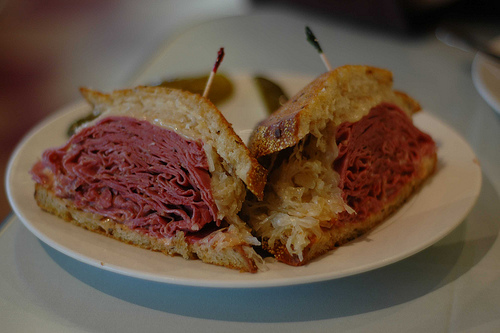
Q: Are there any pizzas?
A: No, there are no pizzas.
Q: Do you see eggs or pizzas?
A: No, there are no pizzas or eggs.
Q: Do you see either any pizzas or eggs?
A: No, there are no pizzas or eggs.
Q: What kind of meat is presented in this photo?
A: The meat is ham.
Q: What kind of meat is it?
A: The meat is ham.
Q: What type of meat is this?
A: This is ham.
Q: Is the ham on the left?
A: Yes, the ham is on the left of the image.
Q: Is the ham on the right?
A: No, the ham is on the left of the image.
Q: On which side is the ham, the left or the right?
A: The ham is on the left of the image.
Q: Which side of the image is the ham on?
A: The ham is on the left of the image.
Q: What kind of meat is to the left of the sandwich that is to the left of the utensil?
A: The meat is ham.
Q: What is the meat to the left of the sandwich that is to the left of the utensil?
A: The meat is ham.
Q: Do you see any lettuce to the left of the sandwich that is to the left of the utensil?
A: No, there is ham to the left of the sandwich.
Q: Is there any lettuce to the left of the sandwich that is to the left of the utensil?
A: No, there is ham to the left of the sandwich.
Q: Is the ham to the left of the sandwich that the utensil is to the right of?
A: Yes, the ham is to the left of the sandwich.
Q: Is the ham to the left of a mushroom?
A: No, the ham is to the left of the sandwich.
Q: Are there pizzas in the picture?
A: No, there are no pizzas.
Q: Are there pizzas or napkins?
A: No, there are no pizzas or napkins.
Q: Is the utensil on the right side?
A: Yes, the utensil is on the right of the image.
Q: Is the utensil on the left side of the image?
A: No, the utensil is on the right of the image.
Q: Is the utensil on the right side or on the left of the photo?
A: The utensil is on the right of the image.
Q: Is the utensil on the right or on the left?
A: The utensil is on the right of the image.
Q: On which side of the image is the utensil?
A: The utensil is on the right of the image.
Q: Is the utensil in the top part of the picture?
A: Yes, the utensil is in the top of the image.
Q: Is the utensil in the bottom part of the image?
A: No, the utensil is in the top of the image.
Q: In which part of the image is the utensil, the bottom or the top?
A: The utensil is in the top of the image.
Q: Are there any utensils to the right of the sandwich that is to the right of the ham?
A: Yes, there is a utensil to the right of the sandwich.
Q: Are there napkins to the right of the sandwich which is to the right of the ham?
A: No, there is a utensil to the right of the sandwich.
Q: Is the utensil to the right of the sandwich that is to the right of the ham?
A: Yes, the utensil is to the right of the sandwich.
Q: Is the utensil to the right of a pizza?
A: No, the utensil is to the right of the sandwich.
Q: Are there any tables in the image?
A: Yes, there is a table.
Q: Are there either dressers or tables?
A: Yes, there is a table.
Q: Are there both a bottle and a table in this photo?
A: No, there is a table but no bottles.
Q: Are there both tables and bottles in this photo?
A: No, there is a table but no bottles.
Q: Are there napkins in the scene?
A: No, there are no napkins.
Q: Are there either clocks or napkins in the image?
A: No, there are no napkins or clocks.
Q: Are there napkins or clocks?
A: No, there are no napkins or clocks.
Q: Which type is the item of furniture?
A: The piece of furniture is a table.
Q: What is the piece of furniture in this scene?
A: The piece of furniture is a table.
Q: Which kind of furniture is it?
A: The piece of furniture is a table.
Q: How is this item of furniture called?
A: This is a table.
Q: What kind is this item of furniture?
A: This is a table.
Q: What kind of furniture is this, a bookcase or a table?
A: This is a table.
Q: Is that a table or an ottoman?
A: That is a table.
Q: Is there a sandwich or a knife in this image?
A: Yes, there is a sandwich.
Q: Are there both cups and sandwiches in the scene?
A: No, there is a sandwich but no cups.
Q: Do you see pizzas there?
A: No, there are no pizzas.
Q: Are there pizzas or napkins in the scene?
A: No, there are no pizzas or napkins.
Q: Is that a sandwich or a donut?
A: That is a sandwich.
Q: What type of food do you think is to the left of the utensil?
A: The food is a sandwich.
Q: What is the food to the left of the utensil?
A: The food is a sandwich.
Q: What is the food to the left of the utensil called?
A: The food is a sandwich.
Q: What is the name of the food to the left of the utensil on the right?
A: The food is a sandwich.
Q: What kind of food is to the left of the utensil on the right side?
A: The food is a sandwich.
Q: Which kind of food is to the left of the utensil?
A: The food is a sandwich.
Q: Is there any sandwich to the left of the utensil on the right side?
A: Yes, there is a sandwich to the left of the utensil.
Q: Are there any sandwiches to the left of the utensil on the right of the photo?
A: Yes, there is a sandwich to the left of the utensil.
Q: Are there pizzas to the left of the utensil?
A: No, there is a sandwich to the left of the utensil.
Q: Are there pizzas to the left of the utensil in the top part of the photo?
A: No, there is a sandwich to the left of the utensil.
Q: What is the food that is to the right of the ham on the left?
A: The food is a sandwich.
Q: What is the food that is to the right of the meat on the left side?
A: The food is a sandwich.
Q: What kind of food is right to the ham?
A: The food is a sandwich.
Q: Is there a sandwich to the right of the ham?
A: Yes, there is a sandwich to the right of the ham.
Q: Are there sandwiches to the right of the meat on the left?
A: Yes, there is a sandwich to the right of the ham.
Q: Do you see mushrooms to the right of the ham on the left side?
A: No, there is a sandwich to the right of the ham.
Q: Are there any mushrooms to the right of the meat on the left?
A: No, there is a sandwich to the right of the ham.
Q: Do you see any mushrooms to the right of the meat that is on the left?
A: No, there is a sandwich to the right of the ham.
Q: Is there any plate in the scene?
A: Yes, there is a plate.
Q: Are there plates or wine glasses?
A: Yes, there is a plate.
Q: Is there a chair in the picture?
A: No, there are no chairs.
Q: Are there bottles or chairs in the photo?
A: No, there are no chairs or bottles.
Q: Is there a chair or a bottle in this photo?
A: No, there are no chairs or bottles.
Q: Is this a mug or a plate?
A: This is a plate.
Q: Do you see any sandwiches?
A: Yes, there is a sandwich.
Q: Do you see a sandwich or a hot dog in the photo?
A: Yes, there is a sandwich.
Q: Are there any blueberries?
A: No, there are no blueberries.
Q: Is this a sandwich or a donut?
A: This is a sandwich.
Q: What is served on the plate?
A: The sandwich is served on the plate.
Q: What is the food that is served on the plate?
A: The food is a sandwich.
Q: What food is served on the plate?
A: The food is a sandwich.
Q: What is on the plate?
A: The sandwich is on the plate.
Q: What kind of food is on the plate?
A: The food is a sandwich.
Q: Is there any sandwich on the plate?
A: Yes, there is a sandwich on the plate.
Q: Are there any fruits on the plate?
A: No, there is a sandwich on the plate.